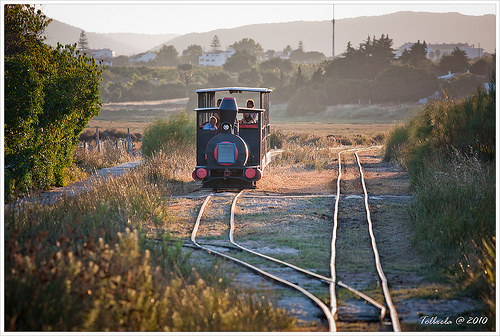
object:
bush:
[406, 144, 498, 261]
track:
[325, 145, 405, 332]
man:
[200, 114, 224, 132]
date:
[466, 314, 487, 325]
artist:
[419, 313, 490, 328]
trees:
[395, 39, 434, 66]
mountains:
[139, 9, 500, 58]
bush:
[4, 0, 60, 201]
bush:
[410, 82, 499, 153]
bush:
[431, 87, 459, 139]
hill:
[383, 77, 497, 332]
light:
[221, 120, 233, 134]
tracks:
[188, 146, 385, 332]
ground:
[4, 88, 487, 332]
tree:
[379, 80, 498, 272]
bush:
[284, 82, 330, 119]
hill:
[100, 45, 461, 119]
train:
[192, 85, 276, 193]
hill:
[271, 62, 498, 122]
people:
[244, 99, 259, 120]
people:
[238, 110, 259, 125]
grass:
[231, 196, 336, 279]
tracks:
[188, 190, 388, 332]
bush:
[41, 39, 112, 186]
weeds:
[412, 144, 496, 268]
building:
[395, 42, 488, 68]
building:
[195, 45, 229, 68]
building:
[126, 49, 160, 68]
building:
[73, 47, 115, 69]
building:
[260, 47, 294, 62]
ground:
[234, 149, 342, 278]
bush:
[381, 117, 412, 161]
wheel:
[238, 161, 263, 192]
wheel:
[192, 161, 223, 188]